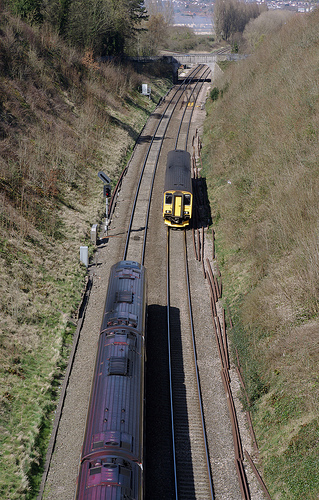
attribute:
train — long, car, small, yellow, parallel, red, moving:
[136, 129, 220, 252]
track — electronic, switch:
[141, 229, 221, 420]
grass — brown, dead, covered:
[256, 125, 286, 177]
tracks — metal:
[169, 223, 202, 322]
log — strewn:
[205, 228, 244, 315]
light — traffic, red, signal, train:
[163, 199, 200, 224]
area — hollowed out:
[74, 221, 114, 312]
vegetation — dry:
[217, 104, 289, 247]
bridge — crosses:
[169, 12, 275, 99]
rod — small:
[187, 234, 231, 325]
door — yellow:
[167, 187, 197, 228]